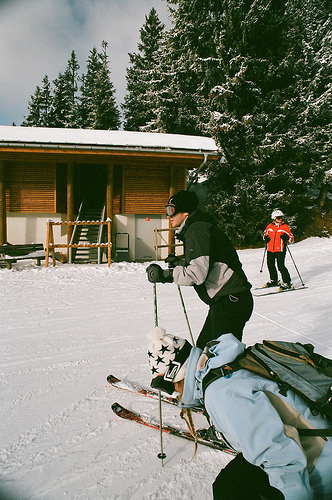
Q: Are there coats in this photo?
A: Yes, there is a coat.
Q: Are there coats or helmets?
A: Yes, there is a coat.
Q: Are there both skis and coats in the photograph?
A: Yes, there are both a coat and skis.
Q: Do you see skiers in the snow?
A: Yes, there is a skier in the snow.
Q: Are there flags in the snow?
A: No, there is a skier in the snow.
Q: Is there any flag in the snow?
A: No, there is a skier in the snow.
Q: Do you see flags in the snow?
A: No, there is a skier in the snow.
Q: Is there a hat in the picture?
A: Yes, there is a hat.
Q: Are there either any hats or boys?
A: Yes, there is a hat.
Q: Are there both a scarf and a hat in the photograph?
A: No, there is a hat but no scarves.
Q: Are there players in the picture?
A: No, there are no players.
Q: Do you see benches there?
A: Yes, there is a bench.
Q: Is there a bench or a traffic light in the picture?
A: Yes, there is a bench.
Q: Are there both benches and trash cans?
A: No, there is a bench but no trash cans.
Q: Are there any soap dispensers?
A: No, there are no soap dispensers.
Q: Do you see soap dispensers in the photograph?
A: No, there are no soap dispensers.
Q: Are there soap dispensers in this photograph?
A: No, there are no soap dispensers.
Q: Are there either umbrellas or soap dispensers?
A: No, there are no soap dispensers or umbrellas.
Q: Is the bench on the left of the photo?
A: Yes, the bench is on the left of the image.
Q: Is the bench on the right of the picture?
A: No, the bench is on the left of the image.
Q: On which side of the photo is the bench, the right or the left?
A: The bench is on the left of the image.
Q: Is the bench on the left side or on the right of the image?
A: The bench is on the left of the image.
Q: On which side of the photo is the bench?
A: The bench is on the left of the image.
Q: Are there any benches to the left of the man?
A: Yes, there is a bench to the left of the man.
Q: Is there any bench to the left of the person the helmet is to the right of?
A: Yes, there is a bench to the left of the man.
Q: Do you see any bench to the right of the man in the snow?
A: No, the bench is to the left of the man.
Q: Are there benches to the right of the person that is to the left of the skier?
A: No, the bench is to the left of the man.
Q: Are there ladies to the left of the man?
A: No, there is a bench to the left of the man.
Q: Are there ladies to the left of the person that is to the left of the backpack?
A: No, there is a bench to the left of the man.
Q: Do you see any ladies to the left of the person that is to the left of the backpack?
A: No, there is a bench to the left of the man.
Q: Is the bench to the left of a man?
A: Yes, the bench is to the left of a man.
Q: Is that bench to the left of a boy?
A: No, the bench is to the left of a man.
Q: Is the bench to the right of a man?
A: No, the bench is to the left of a man.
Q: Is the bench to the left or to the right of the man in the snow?
A: The bench is to the left of the man.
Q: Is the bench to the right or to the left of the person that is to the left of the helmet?
A: The bench is to the left of the man.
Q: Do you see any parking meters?
A: No, there are no parking meters.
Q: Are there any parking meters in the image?
A: No, there are no parking meters.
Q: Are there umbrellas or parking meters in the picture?
A: No, there are no parking meters or umbrellas.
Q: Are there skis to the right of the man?
A: Yes, there is a ski to the right of the man.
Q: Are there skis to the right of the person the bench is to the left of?
A: Yes, there is a ski to the right of the man.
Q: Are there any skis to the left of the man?
A: No, the ski is to the right of the man.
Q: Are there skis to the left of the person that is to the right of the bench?
A: No, the ski is to the right of the man.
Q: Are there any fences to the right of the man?
A: No, there is a ski to the right of the man.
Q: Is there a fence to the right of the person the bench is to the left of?
A: No, there is a ski to the right of the man.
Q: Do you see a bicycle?
A: No, there are no bicycles.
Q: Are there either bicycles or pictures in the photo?
A: No, there are no bicycles or pictures.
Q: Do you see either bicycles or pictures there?
A: No, there are no bicycles or pictures.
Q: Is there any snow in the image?
A: Yes, there is snow.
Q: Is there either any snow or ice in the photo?
A: Yes, there is snow.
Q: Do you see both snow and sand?
A: No, there is snow but no sand.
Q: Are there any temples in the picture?
A: No, there are no temples.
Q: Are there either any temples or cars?
A: No, there are no temples or cars.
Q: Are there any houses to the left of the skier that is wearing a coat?
A: Yes, there is a house to the left of the skier.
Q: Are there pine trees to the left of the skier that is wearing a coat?
A: No, there is a house to the left of the skier.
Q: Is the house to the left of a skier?
A: Yes, the house is to the left of a skier.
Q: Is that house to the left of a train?
A: No, the house is to the left of a skier.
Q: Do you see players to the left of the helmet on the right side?
A: No, there is a house to the left of the helmet.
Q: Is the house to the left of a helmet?
A: Yes, the house is to the left of a helmet.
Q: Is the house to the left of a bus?
A: No, the house is to the left of a helmet.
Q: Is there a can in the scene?
A: No, there are no cans.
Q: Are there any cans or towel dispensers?
A: No, there are no cans or towel dispensers.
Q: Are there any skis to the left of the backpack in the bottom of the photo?
A: Yes, there is a ski to the left of the backpack.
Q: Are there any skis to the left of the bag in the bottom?
A: Yes, there is a ski to the left of the backpack.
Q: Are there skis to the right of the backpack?
A: No, the ski is to the left of the backpack.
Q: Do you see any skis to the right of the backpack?
A: No, the ski is to the left of the backpack.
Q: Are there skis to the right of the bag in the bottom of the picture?
A: No, the ski is to the left of the backpack.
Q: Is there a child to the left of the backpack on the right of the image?
A: No, there is a ski to the left of the backpack.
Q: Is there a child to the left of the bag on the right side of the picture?
A: No, there is a ski to the left of the backpack.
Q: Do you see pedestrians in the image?
A: No, there are no pedestrians.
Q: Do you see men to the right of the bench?
A: Yes, there is a man to the right of the bench.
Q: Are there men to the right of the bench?
A: Yes, there is a man to the right of the bench.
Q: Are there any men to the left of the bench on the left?
A: No, the man is to the right of the bench.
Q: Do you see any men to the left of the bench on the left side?
A: No, the man is to the right of the bench.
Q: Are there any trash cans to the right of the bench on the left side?
A: No, there is a man to the right of the bench.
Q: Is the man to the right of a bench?
A: Yes, the man is to the right of a bench.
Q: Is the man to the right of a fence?
A: No, the man is to the right of a bench.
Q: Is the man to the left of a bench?
A: No, the man is to the right of a bench.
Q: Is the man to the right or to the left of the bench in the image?
A: The man is to the right of the bench.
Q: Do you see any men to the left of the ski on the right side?
A: Yes, there is a man to the left of the ski.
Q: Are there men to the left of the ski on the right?
A: Yes, there is a man to the left of the ski.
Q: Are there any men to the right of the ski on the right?
A: No, the man is to the left of the ski.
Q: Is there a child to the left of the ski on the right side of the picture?
A: No, there is a man to the left of the ski.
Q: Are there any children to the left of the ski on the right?
A: No, there is a man to the left of the ski.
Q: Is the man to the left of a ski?
A: Yes, the man is to the left of a ski.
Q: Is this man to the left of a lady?
A: No, the man is to the left of a ski.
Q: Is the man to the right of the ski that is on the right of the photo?
A: No, the man is to the left of the ski.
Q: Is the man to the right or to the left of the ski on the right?
A: The man is to the left of the ski.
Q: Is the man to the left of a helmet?
A: Yes, the man is to the left of a helmet.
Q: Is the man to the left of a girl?
A: No, the man is to the left of a helmet.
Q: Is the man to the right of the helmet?
A: No, the man is to the left of the helmet.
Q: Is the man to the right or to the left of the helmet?
A: The man is to the left of the helmet.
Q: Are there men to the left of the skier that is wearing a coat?
A: Yes, there is a man to the left of the skier.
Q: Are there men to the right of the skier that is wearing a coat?
A: No, the man is to the left of the skier.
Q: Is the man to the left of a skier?
A: Yes, the man is to the left of a skier.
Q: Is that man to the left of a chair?
A: No, the man is to the left of a skier.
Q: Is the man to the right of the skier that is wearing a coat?
A: No, the man is to the left of the skier.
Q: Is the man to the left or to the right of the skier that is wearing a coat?
A: The man is to the left of the skier.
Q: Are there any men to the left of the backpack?
A: Yes, there is a man to the left of the backpack.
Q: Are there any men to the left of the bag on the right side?
A: Yes, there is a man to the left of the backpack.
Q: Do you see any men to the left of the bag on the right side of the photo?
A: Yes, there is a man to the left of the backpack.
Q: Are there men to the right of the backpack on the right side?
A: No, the man is to the left of the backpack.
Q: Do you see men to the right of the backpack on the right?
A: No, the man is to the left of the backpack.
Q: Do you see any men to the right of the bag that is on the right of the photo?
A: No, the man is to the left of the backpack.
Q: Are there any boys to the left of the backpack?
A: No, there is a man to the left of the backpack.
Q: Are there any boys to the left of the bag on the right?
A: No, there is a man to the left of the backpack.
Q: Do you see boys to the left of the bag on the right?
A: No, there is a man to the left of the backpack.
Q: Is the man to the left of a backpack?
A: Yes, the man is to the left of a backpack.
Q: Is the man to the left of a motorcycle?
A: No, the man is to the left of a backpack.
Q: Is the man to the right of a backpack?
A: No, the man is to the left of a backpack.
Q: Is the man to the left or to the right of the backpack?
A: The man is to the left of the backpack.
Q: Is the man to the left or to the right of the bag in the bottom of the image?
A: The man is to the left of the backpack.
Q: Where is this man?
A: The man is in the snow.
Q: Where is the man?
A: The man is in the snow.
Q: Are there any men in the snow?
A: Yes, there is a man in the snow.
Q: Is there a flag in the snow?
A: No, there is a man in the snow.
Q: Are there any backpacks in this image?
A: Yes, there is a backpack.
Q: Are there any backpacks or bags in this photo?
A: Yes, there is a backpack.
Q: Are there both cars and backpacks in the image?
A: No, there is a backpack but no cars.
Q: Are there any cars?
A: No, there are no cars.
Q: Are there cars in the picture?
A: No, there are no cars.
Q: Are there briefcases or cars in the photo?
A: No, there are no cars or briefcases.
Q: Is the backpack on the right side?
A: Yes, the backpack is on the right of the image.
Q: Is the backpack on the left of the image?
A: No, the backpack is on the right of the image.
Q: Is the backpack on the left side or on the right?
A: The backpack is on the right of the image.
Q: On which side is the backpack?
A: The backpack is on the right of the image.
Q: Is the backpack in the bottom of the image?
A: Yes, the backpack is in the bottom of the image.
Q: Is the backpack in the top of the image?
A: No, the backpack is in the bottom of the image.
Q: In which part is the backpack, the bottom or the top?
A: The backpack is in the bottom of the image.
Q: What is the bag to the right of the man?
A: The bag is a backpack.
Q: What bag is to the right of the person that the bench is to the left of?
A: The bag is a backpack.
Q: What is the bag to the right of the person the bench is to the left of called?
A: The bag is a backpack.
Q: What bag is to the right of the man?
A: The bag is a backpack.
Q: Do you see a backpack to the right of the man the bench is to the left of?
A: Yes, there is a backpack to the right of the man.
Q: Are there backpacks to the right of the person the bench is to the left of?
A: Yes, there is a backpack to the right of the man.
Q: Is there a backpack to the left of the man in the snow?
A: No, the backpack is to the right of the man.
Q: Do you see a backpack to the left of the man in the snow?
A: No, the backpack is to the right of the man.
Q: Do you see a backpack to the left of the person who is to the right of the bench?
A: No, the backpack is to the right of the man.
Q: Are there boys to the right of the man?
A: No, there is a backpack to the right of the man.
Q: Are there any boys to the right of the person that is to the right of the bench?
A: No, there is a backpack to the right of the man.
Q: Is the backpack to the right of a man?
A: Yes, the backpack is to the right of a man.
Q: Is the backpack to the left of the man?
A: No, the backpack is to the right of the man.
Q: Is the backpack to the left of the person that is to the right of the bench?
A: No, the backpack is to the right of the man.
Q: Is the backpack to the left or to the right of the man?
A: The backpack is to the right of the man.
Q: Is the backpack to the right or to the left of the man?
A: The backpack is to the right of the man.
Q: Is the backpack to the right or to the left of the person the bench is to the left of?
A: The backpack is to the right of the man.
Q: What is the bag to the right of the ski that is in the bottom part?
A: The bag is a backpack.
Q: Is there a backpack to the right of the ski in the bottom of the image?
A: Yes, there is a backpack to the right of the ski.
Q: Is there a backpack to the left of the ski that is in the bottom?
A: No, the backpack is to the right of the ski.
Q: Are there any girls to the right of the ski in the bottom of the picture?
A: No, there is a backpack to the right of the ski.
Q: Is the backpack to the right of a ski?
A: Yes, the backpack is to the right of a ski.